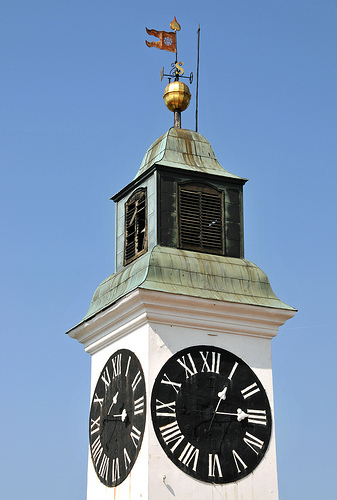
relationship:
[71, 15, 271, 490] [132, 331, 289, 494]
tower has clock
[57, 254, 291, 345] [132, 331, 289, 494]
roof over clock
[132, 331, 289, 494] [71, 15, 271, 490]
clock on tower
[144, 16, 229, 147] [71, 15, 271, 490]
top of tower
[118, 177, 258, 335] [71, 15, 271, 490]
shutter on tower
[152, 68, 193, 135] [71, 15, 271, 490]
shingle on tower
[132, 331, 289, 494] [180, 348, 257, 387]
clock with number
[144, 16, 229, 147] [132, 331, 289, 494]
top of clock